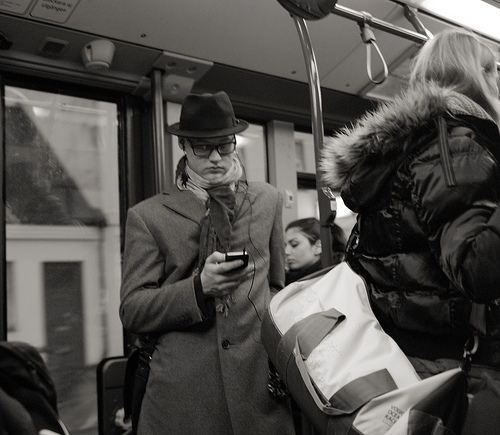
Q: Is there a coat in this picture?
A: Yes, there is a coat.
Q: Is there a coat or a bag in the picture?
A: Yes, there is a coat.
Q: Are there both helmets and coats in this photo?
A: No, there is a coat but no helmets.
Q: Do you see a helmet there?
A: No, there are no helmets.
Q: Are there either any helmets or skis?
A: No, there are no helmets or skis.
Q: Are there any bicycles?
A: No, there are no bicycles.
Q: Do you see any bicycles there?
A: No, there are no bicycles.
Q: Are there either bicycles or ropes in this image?
A: No, there are no bicycles or ropes.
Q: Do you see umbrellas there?
A: No, there are no umbrellas.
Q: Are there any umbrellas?
A: No, there are no umbrellas.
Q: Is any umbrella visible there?
A: No, there are no umbrellas.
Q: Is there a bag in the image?
A: Yes, there is a bag.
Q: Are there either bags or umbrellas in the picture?
A: Yes, there is a bag.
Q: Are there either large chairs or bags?
A: Yes, there is a large bag.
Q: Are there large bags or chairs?
A: Yes, there is a large bag.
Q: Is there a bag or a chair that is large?
A: Yes, the bag is large.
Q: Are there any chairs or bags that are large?
A: Yes, the bag is large.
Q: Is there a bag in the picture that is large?
A: Yes, there is a large bag.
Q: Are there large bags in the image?
A: Yes, there is a large bag.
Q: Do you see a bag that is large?
A: Yes, there is a bag that is large.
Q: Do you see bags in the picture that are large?
A: Yes, there is a bag that is large.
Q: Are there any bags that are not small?
A: Yes, there is a large bag.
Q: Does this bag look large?
A: Yes, the bag is large.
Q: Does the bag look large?
A: Yes, the bag is large.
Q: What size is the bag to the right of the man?
A: The bag is large.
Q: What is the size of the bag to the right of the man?
A: The bag is large.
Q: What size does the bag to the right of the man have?
A: The bag has large size.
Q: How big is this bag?
A: The bag is large.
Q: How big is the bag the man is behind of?
A: The bag is large.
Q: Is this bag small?
A: No, the bag is large.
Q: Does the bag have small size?
A: No, the bag is large.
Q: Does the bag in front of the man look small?
A: No, the bag is large.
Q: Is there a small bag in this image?
A: No, there is a bag but it is large.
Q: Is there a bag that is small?
A: No, there is a bag but it is large.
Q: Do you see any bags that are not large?
A: No, there is a bag but it is large.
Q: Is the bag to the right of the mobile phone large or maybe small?
A: The bag is large.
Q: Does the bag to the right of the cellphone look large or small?
A: The bag is large.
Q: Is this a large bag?
A: Yes, this is a large bag.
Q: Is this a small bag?
A: No, this is a large bag.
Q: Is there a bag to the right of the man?
A: Yes, there is a bag to the right of the man.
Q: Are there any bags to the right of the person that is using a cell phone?
A: Yes, there is a bag to the right of the man.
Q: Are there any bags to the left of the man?
A: No, the bag is to the right of the man.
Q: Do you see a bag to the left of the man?
A: No, the bag is to the right of the man.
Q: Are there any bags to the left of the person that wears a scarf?
A: No, the bag is to the right of the man.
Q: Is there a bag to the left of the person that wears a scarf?
A: No, the bag is to the right of the man.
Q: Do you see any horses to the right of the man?
A: No, there is a bag to the right of the man.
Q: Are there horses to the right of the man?
A: No, there is a bag to the right of the man.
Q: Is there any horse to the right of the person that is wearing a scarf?
A: No, there is a bag to the right of the man.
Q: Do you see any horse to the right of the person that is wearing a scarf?
A: No, there is a bag to the right of the man.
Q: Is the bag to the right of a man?
A: Yes, the bag is to the right of a man.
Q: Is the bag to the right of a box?
A: No, the bag is to the right of a man.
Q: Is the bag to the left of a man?
A: No, the bag is to the right of a man.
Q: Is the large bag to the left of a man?
A: No, the bag is to the right of a man.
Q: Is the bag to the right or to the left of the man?
A: The bag is to the right of the man.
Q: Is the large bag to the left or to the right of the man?
A: The bag is to the right of the man.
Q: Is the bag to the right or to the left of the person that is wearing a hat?
A: The bag is to the right of the man.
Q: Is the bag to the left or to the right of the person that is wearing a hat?
A: The bag is to the right of the man.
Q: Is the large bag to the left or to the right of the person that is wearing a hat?
A: The bag is to the right of the man.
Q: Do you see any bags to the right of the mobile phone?
A: Yes, there is a bag to the right of the mobile phone.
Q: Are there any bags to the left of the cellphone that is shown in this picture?
A: No, the bag is to the right of the cellphone.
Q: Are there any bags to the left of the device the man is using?
A: No, the bag is to the right of the cellphone.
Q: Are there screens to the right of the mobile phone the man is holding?
A: No, there is a bag to the right of the cell phone.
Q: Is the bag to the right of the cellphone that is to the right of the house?
A: Yes, the bag is to the right of the mobile phone.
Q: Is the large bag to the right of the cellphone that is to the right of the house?
A: Yes, the bag is to the right of the mobile phone.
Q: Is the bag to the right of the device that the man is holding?
A: Yes, the bag is to the right of the mobile phone.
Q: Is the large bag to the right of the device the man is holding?
A: Yes, the bag is to the right of the mobile phone.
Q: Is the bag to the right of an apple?
A: No, the bag is to the right of the mobile phone.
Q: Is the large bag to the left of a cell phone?
A: No, the bag is to the right of a cell phone.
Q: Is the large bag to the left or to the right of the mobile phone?
A: The bag is to the right of the mobile phone.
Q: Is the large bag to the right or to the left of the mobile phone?
A: The bag is to the right of the mobile phone.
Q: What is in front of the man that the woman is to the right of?
A: The bag is in front of the man.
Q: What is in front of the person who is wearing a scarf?
A: The bag is in front of the man.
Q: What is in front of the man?
A: The bag is in front of the man.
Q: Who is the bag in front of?
A: The bag is in front of the man.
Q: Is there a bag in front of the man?
A: Yes, there is a bag in front of the man.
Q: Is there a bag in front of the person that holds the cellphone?
A: Yes, there is a bag in front of the man.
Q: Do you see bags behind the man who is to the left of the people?
A: No, the bag is in front of the man.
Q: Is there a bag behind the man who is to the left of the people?
A: No, the bag is in front of the man.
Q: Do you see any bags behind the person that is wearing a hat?
A: No, the bag is in front of the man.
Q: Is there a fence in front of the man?
A: No, there is a bag in front of the man.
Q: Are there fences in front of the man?
A: No, there is a bag in front of the man.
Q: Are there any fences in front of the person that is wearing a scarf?
A: No, there is a bag in front of the man.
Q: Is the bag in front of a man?
A: Yes, the bag is in front of a man.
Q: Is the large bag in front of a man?
A: Yes, the bag is in front of a man.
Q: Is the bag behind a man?
A: No, the bag is in front of a man.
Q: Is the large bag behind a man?
A: No, the bag is in front of a man.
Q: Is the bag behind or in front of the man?
A: The bag is in front of the man.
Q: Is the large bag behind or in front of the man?
A: The bag is in front of the man.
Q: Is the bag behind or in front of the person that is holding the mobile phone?
A: The bag is in front of the man.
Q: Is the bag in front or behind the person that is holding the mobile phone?
A: The bag is in front of the man.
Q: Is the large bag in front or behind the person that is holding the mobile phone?
A: The bag is in front of the man.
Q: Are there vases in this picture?
A: No, there are no vases.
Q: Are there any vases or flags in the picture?
A: No, there are no vases or flags.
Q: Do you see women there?
A: Yes, there is a woman.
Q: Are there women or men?
A: Yes, there is a woman.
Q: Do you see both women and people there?
A: Yes, there are both a woman and people.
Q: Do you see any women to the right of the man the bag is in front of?
A: Yes, there is a woman to the right of the man.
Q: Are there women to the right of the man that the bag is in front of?
A: Yes, there is a woman to the right of the man.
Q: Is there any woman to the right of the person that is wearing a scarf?
A: Yes, there is a woman to the right of the man.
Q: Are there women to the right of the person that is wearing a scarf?
A: Yes, there is a woman to the right of the man.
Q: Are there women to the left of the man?
A: No, the woman is to the right of the man.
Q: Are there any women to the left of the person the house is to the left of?
A: No, the woman is to the right of the man.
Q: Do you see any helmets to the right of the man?
A: No, there is a woman to the right of the man.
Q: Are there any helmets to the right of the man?
A: No, there is a woman to the right of the man.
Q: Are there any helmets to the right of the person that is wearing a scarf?
A: No, there is a woman to the right of the man.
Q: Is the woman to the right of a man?
A: Yes, the woman is to the right of a man.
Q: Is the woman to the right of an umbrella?
A: No, the woman is to the right of a man.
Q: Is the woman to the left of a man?
A: No, the woman is to the right of a man.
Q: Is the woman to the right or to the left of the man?
A: The woman is to the right of the man.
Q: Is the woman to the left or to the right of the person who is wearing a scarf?
A: The woman is to the right of the man.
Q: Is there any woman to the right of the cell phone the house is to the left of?
A: Yes, there is a woman to the right of the cellphone.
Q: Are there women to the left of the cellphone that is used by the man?
A: No, the woman is to the right of the mobile phone.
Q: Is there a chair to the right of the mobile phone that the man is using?
A: No, there is a woman to the right of the cellphone.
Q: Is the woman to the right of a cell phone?
A: Yes, the woman is to the right of a cell phone.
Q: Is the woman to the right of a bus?
A: No, the woman is to the right of a cell phone.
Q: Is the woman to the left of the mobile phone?
A: No, the woman is to the right of the mobile phone.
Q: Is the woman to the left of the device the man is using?
A: No, the woman is to the right of the mobile phone.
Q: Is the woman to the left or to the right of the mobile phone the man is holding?
A: The woman is to the right of the cellphone.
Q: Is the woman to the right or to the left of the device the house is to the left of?
A: The woman is to the right of the cellphone.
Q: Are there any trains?
A: Yes, there is a train.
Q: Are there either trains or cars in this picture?
A: Yes, there is a train.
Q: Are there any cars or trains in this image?
A: Yes, there is a train.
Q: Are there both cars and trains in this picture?
A: No, there is a train but no cars.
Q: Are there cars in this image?
A: No, there are no cars.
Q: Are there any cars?
A: No, there are no cars.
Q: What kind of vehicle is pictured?
A: The vehicle is a train.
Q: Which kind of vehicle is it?
A: The vehicle is a train.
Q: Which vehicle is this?
A: This is a train.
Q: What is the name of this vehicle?
A: This is a train.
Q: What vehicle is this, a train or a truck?
A: This is a train.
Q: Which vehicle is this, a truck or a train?
A: This is a train.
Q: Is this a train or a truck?
A: This is a train.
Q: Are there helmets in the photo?
A: No, there are no helmets.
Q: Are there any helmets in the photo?
A: No, there are no helmets.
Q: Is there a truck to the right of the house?
A: No, there is a man to the right of the house.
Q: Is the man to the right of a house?
A: Yes, the man is to the right of a house.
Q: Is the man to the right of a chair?
A: No, the man is to the right of a house.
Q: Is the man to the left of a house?
A: No, the man is to the right of a house.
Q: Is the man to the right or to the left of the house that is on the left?
A: The man is to the right of the house.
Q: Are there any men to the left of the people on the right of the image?
A: Yes, there is a man to the left of the people.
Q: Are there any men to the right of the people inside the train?
A: No, the man is to the left of the people.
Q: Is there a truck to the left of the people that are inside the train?
A: No, there is a man to the left of the people.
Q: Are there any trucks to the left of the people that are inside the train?
A: No, there is a man to the left of the people.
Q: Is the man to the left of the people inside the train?
A: Yes, the man is to the left of the people.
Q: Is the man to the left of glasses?
A: No, the man is to the left of the people.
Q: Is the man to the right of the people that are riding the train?
A: No, the man is to the left of the people.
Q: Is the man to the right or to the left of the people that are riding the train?
A: The man is to the left of the people.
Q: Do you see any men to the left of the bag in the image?
A: Yes, there is a man to the left of the bag.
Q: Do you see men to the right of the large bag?
A: No, the man is to the left of the bag.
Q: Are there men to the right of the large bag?
A: No, the man is to the left of the bag.